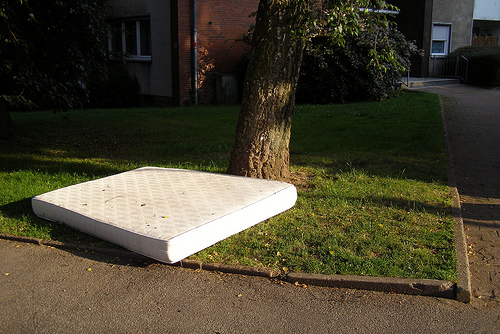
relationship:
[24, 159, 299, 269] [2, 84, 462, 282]
mattress lying on grass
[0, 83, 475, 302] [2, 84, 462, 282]
curb bordering grass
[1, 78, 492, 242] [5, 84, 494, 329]
shadows visible on ground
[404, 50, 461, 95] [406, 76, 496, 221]
puddle on ground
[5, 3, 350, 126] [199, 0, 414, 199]
building behind tree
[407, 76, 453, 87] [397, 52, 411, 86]
step has rail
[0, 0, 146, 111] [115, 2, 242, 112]
bush on side of building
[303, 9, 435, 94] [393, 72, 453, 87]
bush next to step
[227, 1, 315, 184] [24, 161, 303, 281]
bark next to mattress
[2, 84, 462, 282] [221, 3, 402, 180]
grass next to tree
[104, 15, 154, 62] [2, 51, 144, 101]
window next to bush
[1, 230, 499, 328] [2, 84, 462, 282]
road next to grass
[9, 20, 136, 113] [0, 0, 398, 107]
tree by building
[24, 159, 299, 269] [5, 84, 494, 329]
mattress on ground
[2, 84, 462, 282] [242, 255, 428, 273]
grass on ground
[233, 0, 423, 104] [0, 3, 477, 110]
bush beside building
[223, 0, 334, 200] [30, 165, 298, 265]
tree beside mattress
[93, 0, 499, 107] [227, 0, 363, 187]
building behind tree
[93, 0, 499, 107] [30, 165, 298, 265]
building behind mattress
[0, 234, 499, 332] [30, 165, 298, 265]
sidewalk in front of mattress